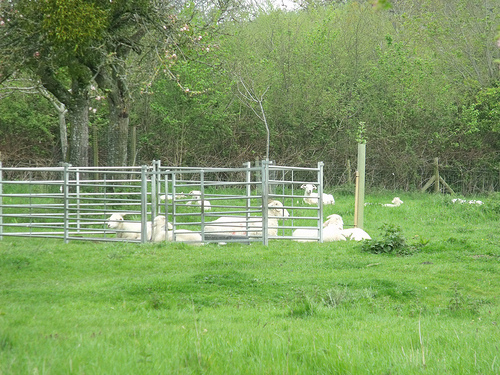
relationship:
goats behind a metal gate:
[299, 182, 337, 207] [157, 157, 268, 245]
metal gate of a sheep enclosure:
[0, 166, 322, 241] [1, 155, 498, 232]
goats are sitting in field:
[299, 182, 337, 207] [6, 180, 496, 373]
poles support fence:
[420, 155, 454, 195] [322, 164, 494, 195]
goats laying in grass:
[326, 204, 371, 240] [4, 184, 499, 373]